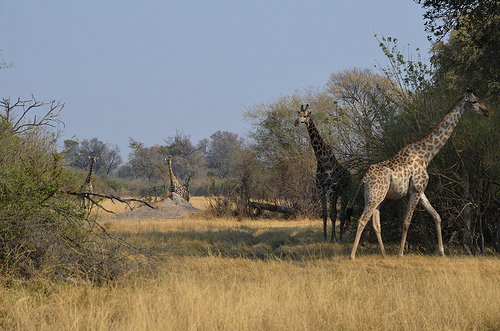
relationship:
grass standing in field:
[0, 195, 499, 330] [1, 190, 496, 326]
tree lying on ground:
[235, 170, 298, 220] [0, 194, 496, 326]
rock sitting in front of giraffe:
[108, 190, 198, 220] [162, 153, 189, 203]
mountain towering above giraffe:
[418, 0, 495, 249] [350, 89, 489, 257]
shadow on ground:
[248, 231, 302, 252] [222, 264, 274, 300]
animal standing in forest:
[347, 88, 489, 261] [0, 0, 167, 290]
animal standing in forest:
[293, 103, 355, 243] [116, 1, 498, 251]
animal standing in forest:
[166, 153, 188, 200] [116, 1, 498, 251]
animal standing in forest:
[78, 156, 96, 214] [116, 1, 498, 251]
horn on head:
[303, 102, 308, 110] [293, 103, 310, 125]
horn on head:
[297, 103, 304, 110] [293, 103, 310, 125]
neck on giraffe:
[306, 123, 341, 177] [277, 84, 364, 253]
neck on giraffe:
[424, 102, 468, 161] [344, 90, 499, 262]